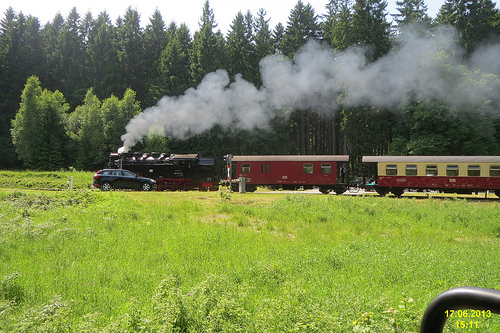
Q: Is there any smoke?
A: Yes, there is smoke.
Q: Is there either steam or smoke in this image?
A: Yes, there is smoke.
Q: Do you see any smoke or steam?
A: Yes, there is smoke.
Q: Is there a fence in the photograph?
A: No, there are no fences.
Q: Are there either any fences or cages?
A: No, there are no fences or cages.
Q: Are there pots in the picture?
A: No, there are no pots.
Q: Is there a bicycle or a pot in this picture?
A: No, there are no pots or bicycles.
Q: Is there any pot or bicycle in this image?
A: No, there are no pots or bicycles.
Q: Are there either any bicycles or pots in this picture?
A: No, there are no pots or bicycles.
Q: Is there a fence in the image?
A: No, there are no fences.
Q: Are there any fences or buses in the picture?
A: No, there are no fences or buses.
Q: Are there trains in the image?
A: Yes, there is a train.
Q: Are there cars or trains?
A: Yes, there is a train.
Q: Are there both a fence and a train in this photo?
A: No, there is a train but no fences.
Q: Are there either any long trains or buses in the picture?
A: Yes, there is a long train.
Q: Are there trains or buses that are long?
A: Yes, the train is long.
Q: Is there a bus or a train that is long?
A: Yes, the train is long.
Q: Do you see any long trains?
A: Yes, there is a long train.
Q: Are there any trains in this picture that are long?
A: Yes, there is a train that is long.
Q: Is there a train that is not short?
A: Yes, there is a long train.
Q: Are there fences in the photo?
A: No, there are no fences.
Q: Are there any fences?
A: No, there are no fences.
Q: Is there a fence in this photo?
A: No, there are no fences.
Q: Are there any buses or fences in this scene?
A: No, there are no fences or buses.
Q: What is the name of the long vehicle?
A: The vehicle is a train.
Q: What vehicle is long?
A: The vehicle is a train.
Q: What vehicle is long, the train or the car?
A: The train is long.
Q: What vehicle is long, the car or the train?
A: The train is long.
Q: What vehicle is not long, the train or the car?
A: The car is not long.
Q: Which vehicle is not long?
A: The vehicle is a car.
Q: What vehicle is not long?
A: The vehicle is a car.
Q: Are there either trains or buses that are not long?
A: No, there is a train but it is long.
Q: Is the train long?
A: Yes, the train is long.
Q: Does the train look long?
A: Yes, the train is long.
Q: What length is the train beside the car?
A: The train is long.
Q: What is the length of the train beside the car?
A: The train is long.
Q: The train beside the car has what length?
A: The train is long.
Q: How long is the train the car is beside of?
A: The train is long.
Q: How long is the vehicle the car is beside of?
A: The train is long.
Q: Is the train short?
A: No, the train is long.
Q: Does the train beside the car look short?
A: No, the train is long.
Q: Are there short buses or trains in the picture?
A: No, there is a train but it is long.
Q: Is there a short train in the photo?
A: No, there is a train but it is long.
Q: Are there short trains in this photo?
A: No, there is a train but it is long.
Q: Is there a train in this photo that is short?
A: No, there is a train but it is long.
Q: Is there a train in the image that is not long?
A: No, there is a train but it is long.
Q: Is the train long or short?
A: The train is long.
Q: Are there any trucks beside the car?
A: No, there is a train beside the car.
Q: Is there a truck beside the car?
A: No, there is a train beside the car.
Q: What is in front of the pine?
A: The train is in front of the pine.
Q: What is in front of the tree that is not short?
A: The train is in front of the pine.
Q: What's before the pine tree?
A: The train is in front of the pine.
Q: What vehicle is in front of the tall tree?
A: The vehicle is a train.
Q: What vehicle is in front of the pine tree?
A: The vehicle is a train.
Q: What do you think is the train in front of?
A: The train is in front of the pine tree.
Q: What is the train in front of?
A: The train is in front of the pine tree.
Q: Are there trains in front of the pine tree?
A: Yes, there is a train in front of the pine tree.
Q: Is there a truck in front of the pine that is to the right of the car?
A: No, there is a train in front of the pine tree.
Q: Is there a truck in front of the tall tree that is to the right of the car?
A: No, there is a train in front of the pine tree.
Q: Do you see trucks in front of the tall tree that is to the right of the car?
A: No, there is a train in front of the pine tree.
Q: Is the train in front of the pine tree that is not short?
A: Yes, the train is in front of the pine tree.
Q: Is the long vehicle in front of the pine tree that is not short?
A: Yes, the train is in front of the pine tree.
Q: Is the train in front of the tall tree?
A: Yes, the train is in front of the pine tree.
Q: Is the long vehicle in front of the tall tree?
A: Yes, the train is in front of the pine tree.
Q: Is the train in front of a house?
A: No, the train is in front of the pine tree.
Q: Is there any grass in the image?
A: Yes, there is grass.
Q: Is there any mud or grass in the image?
A: Yes, there is grass.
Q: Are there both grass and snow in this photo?
A: No, there is grass but no snow.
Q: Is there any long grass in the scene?
A: Yes, there is long grass.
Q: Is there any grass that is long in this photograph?
A: Yes, there is long grass.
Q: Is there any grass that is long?
A: Yes, there is grass that is long.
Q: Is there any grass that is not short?
A: Yes, there is long grass.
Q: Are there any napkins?
A: No, there are no napkins.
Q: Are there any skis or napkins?
A: No, there are no napkins or skis.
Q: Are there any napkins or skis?
A: No, there are no napkins or skis.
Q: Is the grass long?
A: Yes, the grass is long.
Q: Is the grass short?
A: No, the grass is long.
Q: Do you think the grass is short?
A: No, the grass is long.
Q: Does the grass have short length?
A: No, the grass is long.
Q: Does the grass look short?
A: No, the grass is long.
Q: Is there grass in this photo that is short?
A: No, there is grass but it is long.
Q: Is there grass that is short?
A: No, there is grass but it is long.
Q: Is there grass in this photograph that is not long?
A: No, there is grass but it is long.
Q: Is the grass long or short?
A: The grass is long.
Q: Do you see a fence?
A: No, there are no fences.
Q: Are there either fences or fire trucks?
A: No, there are no fences or fire trucks.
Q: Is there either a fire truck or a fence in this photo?
A: No, there are no fences or fire trucks.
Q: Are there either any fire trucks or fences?
A: No, there are no fences or fire trucks.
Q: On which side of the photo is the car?
A: The car is on the left of the image.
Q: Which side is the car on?
A: The car is on the left of the image.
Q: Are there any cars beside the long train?
A: Yes, there is a car beside the train.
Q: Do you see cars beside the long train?
A: Yes, there is a car beside the train.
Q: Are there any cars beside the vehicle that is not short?
A: Yes, there is a car beside the train.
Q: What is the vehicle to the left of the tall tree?
A: The vehicle is a car.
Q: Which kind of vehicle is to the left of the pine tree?
A: The vehicle is a car.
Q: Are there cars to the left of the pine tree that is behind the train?
A: Yes, there is a car to the left of the pine tree.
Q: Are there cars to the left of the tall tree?
A: Yes, there is a car to the left of the pine tree.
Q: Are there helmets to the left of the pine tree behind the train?
A: No, there is a car to the left of the pine.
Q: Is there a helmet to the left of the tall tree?
A: No, there is a car to the left of the pine.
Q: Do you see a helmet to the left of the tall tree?
A: No, there is a car to the left of the pine.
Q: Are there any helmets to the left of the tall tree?
A: No, there is a car to the left of the pine.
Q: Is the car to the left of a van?
A: No, the car is to the left of the pine.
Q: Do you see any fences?
A: No, there are no fences.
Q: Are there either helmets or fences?
A: No, there are no fences or helmets.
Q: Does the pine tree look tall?
A: Yes, the pine tree is tall.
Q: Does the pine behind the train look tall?
A: Yes, the pine is tall.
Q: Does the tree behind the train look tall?
A: Yes, the pine is tall.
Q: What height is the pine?
A: The pine is tall.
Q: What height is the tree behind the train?
A: The pine is tall.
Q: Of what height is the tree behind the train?
A: The pine is tall.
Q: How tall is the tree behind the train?
A: The pine tree is tall.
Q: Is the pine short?
A: No, the pine is tall.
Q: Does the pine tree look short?
A: No, the pine tree is tall.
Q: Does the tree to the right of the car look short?
A: No, the pine tree is tall.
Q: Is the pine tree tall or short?
A: The pine tree is tall.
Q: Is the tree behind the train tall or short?
A: The pine tree is tall.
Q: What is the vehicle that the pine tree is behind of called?
A: The vehicle is a train.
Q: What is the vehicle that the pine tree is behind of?
A: The vehicle is a train.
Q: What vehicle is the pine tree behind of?
A: The pine tree is behind the train.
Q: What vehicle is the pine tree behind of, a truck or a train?
A: The pine tree is behind a train.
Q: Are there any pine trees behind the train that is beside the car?
A: Yes, there is a pine tree behind the train.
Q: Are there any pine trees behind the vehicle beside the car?
A: Yes, there is a pine tree behind the train.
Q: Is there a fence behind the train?
A: No, there is a pine tree behind the train.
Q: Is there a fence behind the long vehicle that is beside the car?
A: No, there is a pine tree behind the train.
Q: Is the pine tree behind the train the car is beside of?
A: Yes, the pine tree is behind the train.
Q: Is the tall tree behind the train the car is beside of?
A: Yes, the pine tree is behind the train.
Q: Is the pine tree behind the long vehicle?
A: Yes, the pine tree is behind the train.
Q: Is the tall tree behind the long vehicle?
A: Yes, the pine tree is behind the train.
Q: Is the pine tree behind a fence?
A: No, the pine tree is behind the train.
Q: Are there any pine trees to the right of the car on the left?
A: Yes, there is a pine tree to the right of the car.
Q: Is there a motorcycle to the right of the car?
A: No, there is a pine tree to the right of the car.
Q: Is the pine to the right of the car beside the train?
A: Yes, the pine is to the right of the car.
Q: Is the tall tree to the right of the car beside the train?
A: Yes, the pine is to the right of the car.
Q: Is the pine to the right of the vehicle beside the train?
A: Yes, the pine is to the right of the car.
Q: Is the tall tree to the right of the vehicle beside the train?
A: Yes, the pine is to the right of the car.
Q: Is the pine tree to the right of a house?
A: No, the pine tree is to the right of the car.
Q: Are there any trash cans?
A: No, there are no trash cans.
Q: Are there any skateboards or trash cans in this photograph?
A: No, there are no trash cans or skateboards.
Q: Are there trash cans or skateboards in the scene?
A: No, there are no trash cans or skateboards.